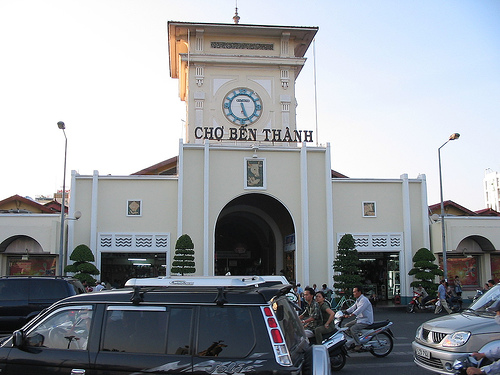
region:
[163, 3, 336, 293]
a tall white asian tower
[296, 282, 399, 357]
bikers pulling into a parking lot spot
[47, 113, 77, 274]
a tall street light pole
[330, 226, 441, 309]
a small entrance behind some trees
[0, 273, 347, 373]
a black suv in a parking lot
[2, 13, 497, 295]
a large asian market place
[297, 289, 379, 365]
people on the bikes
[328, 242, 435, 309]
trees in front of building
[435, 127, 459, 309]
light on the pole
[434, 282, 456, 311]
the man is walking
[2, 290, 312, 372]
the cars are parked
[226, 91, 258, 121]
the clock face is white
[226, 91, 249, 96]
the numbers are blue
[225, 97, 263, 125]
numbers on the clock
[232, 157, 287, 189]
mosaic on the building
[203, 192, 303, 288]
arch in the building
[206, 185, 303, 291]
archway in front of a building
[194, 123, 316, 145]
letters on the front of a building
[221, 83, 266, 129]
clock on a building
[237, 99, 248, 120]
blue hands of a clock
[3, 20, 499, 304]
large yellow and white building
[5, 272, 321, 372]
black SUV with a hood rack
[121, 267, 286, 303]
silver hood rack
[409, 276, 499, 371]
silver vehicle on the road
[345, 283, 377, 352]
bike rider with a white shirt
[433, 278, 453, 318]
man with a blue shirt and khaki pants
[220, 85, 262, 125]
clock on front of the building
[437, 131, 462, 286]
street light on the sidewalk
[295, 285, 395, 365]
people riding motor cycles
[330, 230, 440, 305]
unusual trimmed trees by entrance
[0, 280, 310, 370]
black station wagon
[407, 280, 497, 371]
silver gray vehicle on street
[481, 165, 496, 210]
tall building in the distance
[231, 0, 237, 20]
lightening rod on top of building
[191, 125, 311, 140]
lack writing on front of building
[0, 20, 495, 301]
beige building with white trim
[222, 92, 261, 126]
white clock face on yellow building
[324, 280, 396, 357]
man in white shirt on motorbike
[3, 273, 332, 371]
black SUV in the foreground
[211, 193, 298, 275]
arched entrance to yellow building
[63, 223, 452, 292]
four green topiaries outside building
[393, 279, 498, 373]
silver SUV on the street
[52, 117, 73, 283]
silver light pole near building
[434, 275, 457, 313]
man walking in blue shirt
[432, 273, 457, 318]
man walking in khaki pants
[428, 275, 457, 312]
man walking carrying white bag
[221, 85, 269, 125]
white clock face in yellow building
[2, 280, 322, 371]
black SUV on street in foreground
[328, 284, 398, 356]
man in white shirt on silver motorbike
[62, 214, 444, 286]
four green topiary trees in front of yellow building